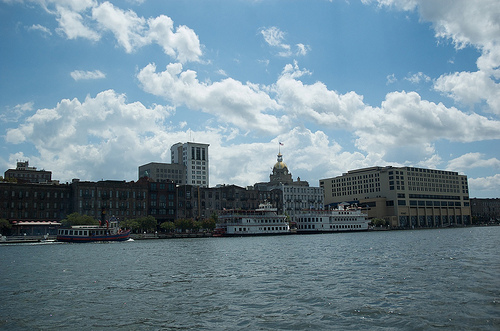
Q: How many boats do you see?
A: 3.